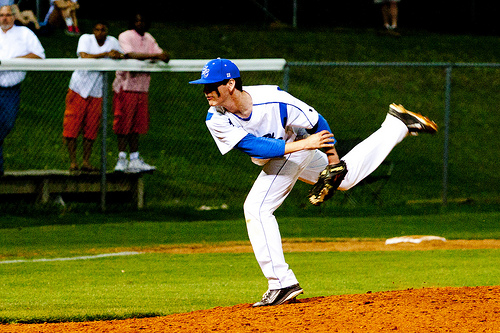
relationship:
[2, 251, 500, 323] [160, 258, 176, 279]
grass has part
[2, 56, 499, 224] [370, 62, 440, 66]
fence has part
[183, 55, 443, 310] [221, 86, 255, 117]
pitcher has neck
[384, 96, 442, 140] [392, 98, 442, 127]
shoe has edge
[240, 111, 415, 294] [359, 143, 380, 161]
pants have part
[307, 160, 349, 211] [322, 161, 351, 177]
glove has part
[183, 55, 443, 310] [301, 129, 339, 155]
pitcher has hand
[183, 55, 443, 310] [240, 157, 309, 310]
pitcher has leg